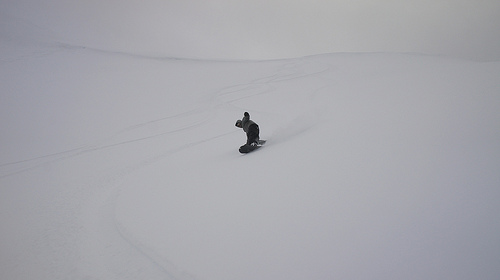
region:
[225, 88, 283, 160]
Man on a snow board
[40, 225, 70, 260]
Snow covering the ground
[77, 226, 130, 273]
Snow covering the ground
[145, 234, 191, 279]
Snow covering the ground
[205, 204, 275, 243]
Snow covering the ground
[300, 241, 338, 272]
Snow covering the ground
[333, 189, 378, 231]
Snow covering the ground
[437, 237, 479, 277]
Snow covering the ground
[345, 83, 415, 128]
Snow covering the ground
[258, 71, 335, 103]
Snow covering the ground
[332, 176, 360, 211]
patch of white snow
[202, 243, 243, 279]
patch of white snow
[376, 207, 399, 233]
patch of white snow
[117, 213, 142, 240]
patch of white snow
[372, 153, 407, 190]
patch of white snow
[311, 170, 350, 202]
patch of white snow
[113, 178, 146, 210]
patch of white snow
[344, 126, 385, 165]
patch of white snow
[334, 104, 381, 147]
patch of white snow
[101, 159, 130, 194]
patch of white snow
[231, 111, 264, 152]
a man on a snowboard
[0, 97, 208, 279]
ski trails in powdery snow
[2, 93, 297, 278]
a man snowboarding on a snowy mountain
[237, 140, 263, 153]
a black snowboard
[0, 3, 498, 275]
a large snow covered mountain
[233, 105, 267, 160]
a man trying to keep his balance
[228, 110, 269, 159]
a man in full snow gear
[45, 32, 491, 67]
a winding line of snow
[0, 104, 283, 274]
a man snowboarding down a winding mountain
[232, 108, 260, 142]
man leaning over skateboarding in snow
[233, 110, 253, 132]
man in cream colored jacket with hood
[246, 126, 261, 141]
man wearing black snow pants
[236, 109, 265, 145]
man with left arm and hand outstretched in air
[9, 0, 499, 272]
plain white snow covering ground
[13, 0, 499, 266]
grey bleak overcast day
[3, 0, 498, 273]
black and white photograph of snowboarder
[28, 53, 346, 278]
lines in snow from previous snowboarding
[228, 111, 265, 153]
white boy on black snow board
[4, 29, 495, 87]
dip on horizon of mountain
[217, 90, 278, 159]
A snow boarder on a slope.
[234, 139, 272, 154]
a board on snow.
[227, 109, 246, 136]
a man with short hair.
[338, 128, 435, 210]
a snow covered ski slope.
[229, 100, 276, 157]
a snowboarder on snow.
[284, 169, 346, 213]
white snow on the ground.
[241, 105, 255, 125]
a right human arm.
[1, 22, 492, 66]
the top of a snow covered slope.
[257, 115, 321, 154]
a shadow cast in the snow.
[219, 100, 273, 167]
a man riding a snowboard.